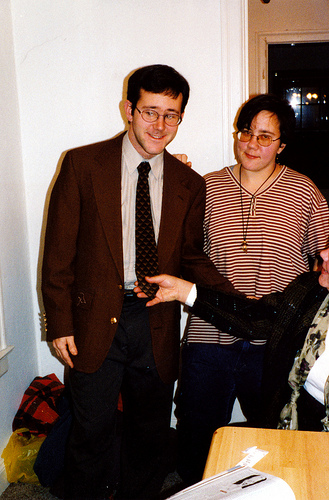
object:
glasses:
[131, 102, 182, 127]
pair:
[127, 106, 183, 129]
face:
[133, 96, 176, 158]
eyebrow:
[164, 107, 180, 117]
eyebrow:
[237, 127, 254, 132]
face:
[234, 121, 276, 172]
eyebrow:
[257, 129, 277, 135]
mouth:
[147, 133, 168, 145]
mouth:
[241, 150, 262, 158]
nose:
[247, 135, 259, 150]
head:
[121, 62, 191, 155]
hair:
[125, 62, 190, 114]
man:
[39, 60, 265, 497]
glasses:
[238, 132, 281, 147]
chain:
[238, 162, 275, 254]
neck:
[237, 156, 274, 181]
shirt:
[179, 165, 328, 347]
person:
[172, 96, 327, 484]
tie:
[133, 159, 161, 300]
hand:
[170, 152, 190, 170]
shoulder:
[168, 158, 208, 209]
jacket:
[39, 128, 246, 388]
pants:
[61, 297, 175, 497]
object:
[11, 370, 65, 434]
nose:
[154, 113, 166, 134]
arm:
[40, 149, 80, 338]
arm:
[179, 173, 247, 303]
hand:
[48, 333, 78, 371]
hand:
[240, 291, 265, 303]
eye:
[146, 109, 154, 118]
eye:
[164, 111, 175, 120]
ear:
[123, 98, 135, 123]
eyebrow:
[139, 104, 160, 111]